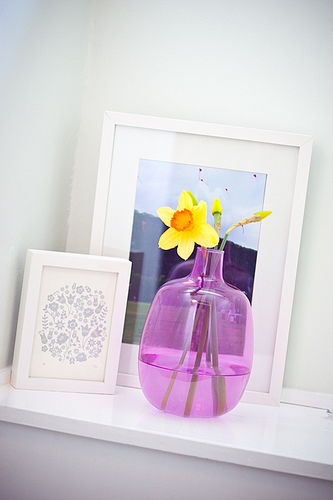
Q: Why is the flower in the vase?
A: For the water.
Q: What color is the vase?
A: Pretty pink.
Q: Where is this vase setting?
A: On a table top.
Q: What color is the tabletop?
A: Pure white.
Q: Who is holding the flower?
A: No one.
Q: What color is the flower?
A: They are yellow.